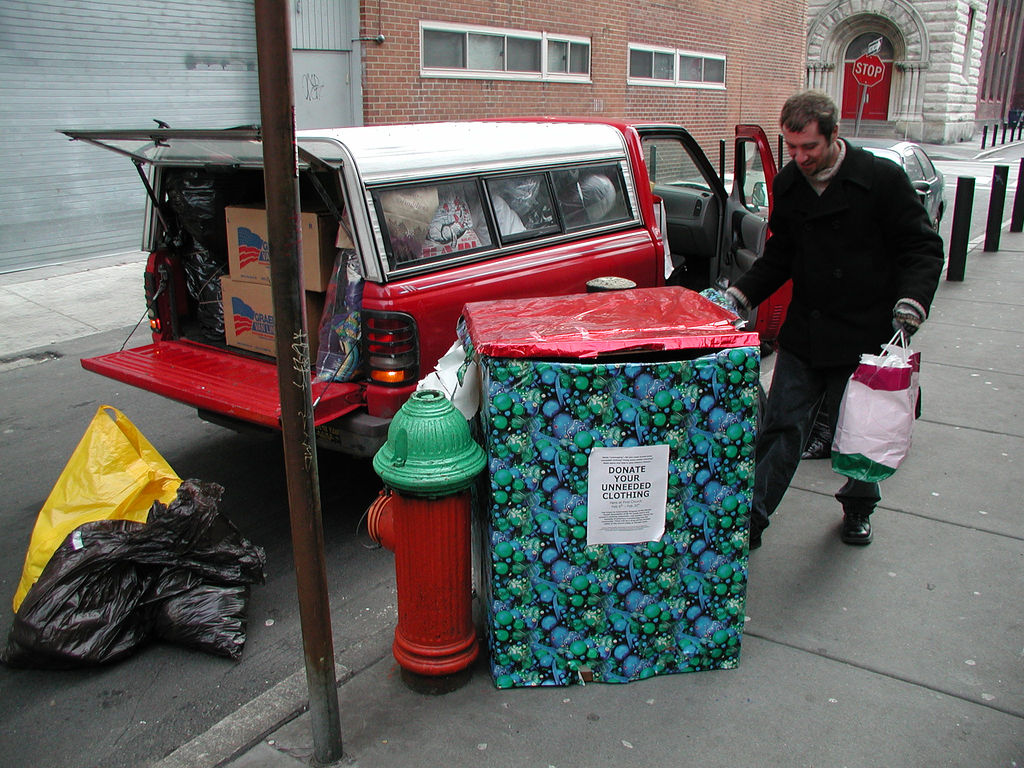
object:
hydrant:
[354, 389, 489, 696]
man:
[718, 90, 942, 551]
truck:
[50, 118, 779, 459]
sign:
[852, 53, 887, 138]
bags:
[6, 479, 269, 670]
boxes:
[217, 206, 338, 366]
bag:
[830, 328, 921, 483]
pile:
[0, 401, 268, 674]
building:
[361, 0, 805, 184]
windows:
[417, 20, 589, 84]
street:
[0, 96, 1021, 767]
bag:
[13, 404, 185, 613]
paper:
[586, 444, 669, 546]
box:
[458, 284, 757, 690]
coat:
[725, 137, 944, 374]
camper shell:
[54, 118, 646, 287]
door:
[714, 124, 779, 294]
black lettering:
[599, 455, 656, 533]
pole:
[252, 0, 345, 764]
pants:
[750, 307, 882, 540]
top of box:
[462, 286, 763, 360]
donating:
[610, 466, 646, 474]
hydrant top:
[372, 390, 489, 498]